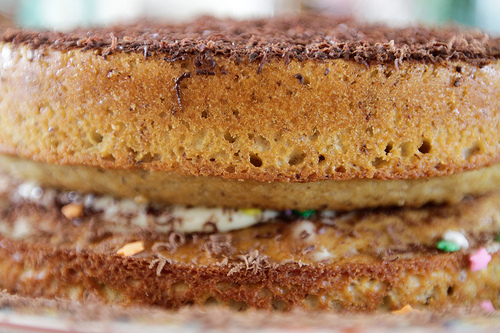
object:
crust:
[0, 34, 500, 183]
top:
[0, 10, 500, 66]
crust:
[2, 11, 499, 58]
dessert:
[1, 11, 498, 331]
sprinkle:
[292, 220, 314, 236]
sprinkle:
[486, 241, 498, 251]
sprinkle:
[307, 244, 333, 259]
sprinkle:
[321, 211, 336, 224]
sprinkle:
[465, 247, 499, 274]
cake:
[0, 206, 500, 331]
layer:
[0, 63, 482, 170]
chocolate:
[0, 10, 500, 62]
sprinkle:
[59, 195, 83, 222]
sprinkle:
[430, 226, 470, 255]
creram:
[3, 23, 500, 330]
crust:
[0, 238, 500, 327]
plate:
[0, 289, 500, 333]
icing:
[8, 174, 274, 236]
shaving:
[1, 172, 500, 271]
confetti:
[428, 224, 476, 258]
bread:
[0, 25, 495, 216]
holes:
[243, 150, 265, 171]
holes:
[413, 138, 438, 156]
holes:
[308, 151, 331, 165]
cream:
[432, 225, 472, 255]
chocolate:
[2, 225, 478, 287]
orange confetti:
[111, 239, 145, 262]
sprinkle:
[108, 232, 153, 266]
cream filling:
[12, 180, 280, 236]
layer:
[2, 191, 499, 331]